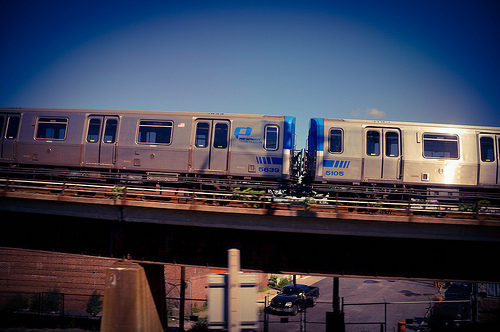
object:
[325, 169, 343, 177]
number 5105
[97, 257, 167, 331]
support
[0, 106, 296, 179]
train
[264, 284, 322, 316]
truck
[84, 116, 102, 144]
window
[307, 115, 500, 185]
train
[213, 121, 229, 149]
window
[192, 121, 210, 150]
window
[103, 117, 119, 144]
window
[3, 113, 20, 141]
window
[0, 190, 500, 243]
bridge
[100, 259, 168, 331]
brick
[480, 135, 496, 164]
window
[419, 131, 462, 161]
window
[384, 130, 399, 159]
window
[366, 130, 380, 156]
window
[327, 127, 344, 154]
window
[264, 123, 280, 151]
window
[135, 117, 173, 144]
window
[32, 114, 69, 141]
train window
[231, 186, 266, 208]
shrubs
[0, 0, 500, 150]
sky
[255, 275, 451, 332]
roadway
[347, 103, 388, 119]
cloud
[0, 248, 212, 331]
building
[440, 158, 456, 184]
sun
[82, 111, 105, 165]
doors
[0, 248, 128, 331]
wall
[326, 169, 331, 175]
number